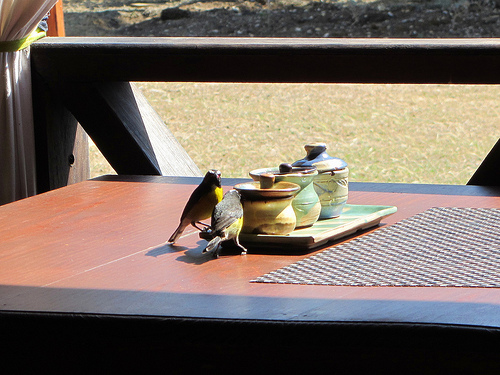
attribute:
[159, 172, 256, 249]
birds — yellow, small, black, standing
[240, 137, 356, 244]
jars — small, clay, wooden, multi-colored, decorative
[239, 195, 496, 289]
mat — woven, patterned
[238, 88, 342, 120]
grass — dry, brown, on hill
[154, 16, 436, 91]
rail — wooden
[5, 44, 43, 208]
curtain — white, small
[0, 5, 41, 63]
tie — green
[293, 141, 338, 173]
lid — blue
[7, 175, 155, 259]
table — brown, light brown, dark brown, wooden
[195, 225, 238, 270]
tail — grey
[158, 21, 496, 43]
trees — shadowed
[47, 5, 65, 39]
frame — wooden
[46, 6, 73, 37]
window — open